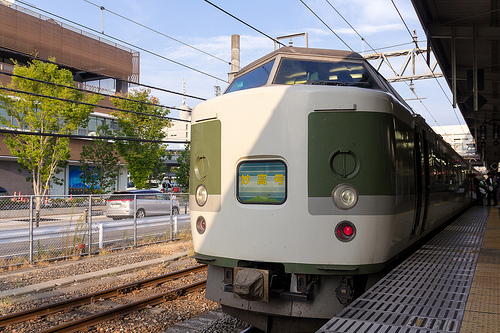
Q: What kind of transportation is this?
A: Train.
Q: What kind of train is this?
A: Passenger.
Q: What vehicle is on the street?
A: A van.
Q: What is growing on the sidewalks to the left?
A: Trees.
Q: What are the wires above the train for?
A: For running the train.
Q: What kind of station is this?
A: Train station.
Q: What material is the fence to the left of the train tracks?
A: Metal.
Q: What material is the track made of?
A: Steel.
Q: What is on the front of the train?
A: Lights.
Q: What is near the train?
A: Trees.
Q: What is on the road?
A: A car.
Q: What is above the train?
A: Wires.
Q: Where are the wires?
A: Above the train.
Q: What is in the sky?
A: Clouds.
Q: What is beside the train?
A: A platform.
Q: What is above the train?
A: Power lines.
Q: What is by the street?
A: Two trees.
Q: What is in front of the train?
A: Lights on the train.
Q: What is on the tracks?
A: Gravel.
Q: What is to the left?
A: A building.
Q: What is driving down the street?
A: A car.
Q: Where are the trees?
A: On the sidewalk.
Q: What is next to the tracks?
A: Metal fencing.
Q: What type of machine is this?
A: A train.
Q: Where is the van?
A: On the road.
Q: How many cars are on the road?
A: One.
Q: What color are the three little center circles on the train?
A: Yellow.